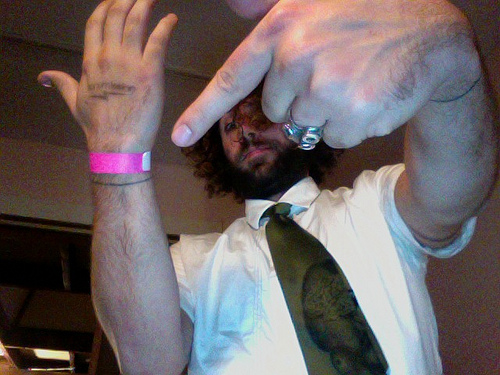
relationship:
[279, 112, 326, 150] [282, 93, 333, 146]
ring on finger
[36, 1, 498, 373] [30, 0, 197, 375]
man has arm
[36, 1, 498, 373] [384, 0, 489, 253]
man has arm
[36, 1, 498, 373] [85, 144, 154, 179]
man has wristband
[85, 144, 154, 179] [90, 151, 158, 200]
wristband on wrist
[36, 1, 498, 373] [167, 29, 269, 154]
man pointing with finger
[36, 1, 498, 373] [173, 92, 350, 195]
man has hair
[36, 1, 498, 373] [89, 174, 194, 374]
man has arm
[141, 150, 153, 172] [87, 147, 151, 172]
white part of band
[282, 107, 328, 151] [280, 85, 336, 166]
ring in finger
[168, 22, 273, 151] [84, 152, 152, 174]
finger pointing to band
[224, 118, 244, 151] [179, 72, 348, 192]
hair hanging in front of face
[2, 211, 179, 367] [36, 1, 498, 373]
door behind man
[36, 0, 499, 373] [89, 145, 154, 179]
man wearing wrist band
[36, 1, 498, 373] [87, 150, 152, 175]
man wearing pink wristband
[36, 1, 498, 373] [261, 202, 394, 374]
man wearing green tie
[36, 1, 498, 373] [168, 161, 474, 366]
man wearing white shirt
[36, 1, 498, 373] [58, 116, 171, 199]
man pointing at wrist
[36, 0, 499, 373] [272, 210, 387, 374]
man wearing tie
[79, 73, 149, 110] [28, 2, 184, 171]
tattoo on hand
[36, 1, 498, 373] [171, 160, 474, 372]
man wearing shirt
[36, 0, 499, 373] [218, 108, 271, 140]
man wearing glasses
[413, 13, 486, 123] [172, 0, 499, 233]
hair on hand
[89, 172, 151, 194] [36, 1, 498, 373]
line around man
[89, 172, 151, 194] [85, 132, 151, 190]
line around wrist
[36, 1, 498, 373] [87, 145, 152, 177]
man wearing band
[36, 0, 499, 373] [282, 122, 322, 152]
man wearing ring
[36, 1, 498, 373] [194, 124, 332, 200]
man has hair